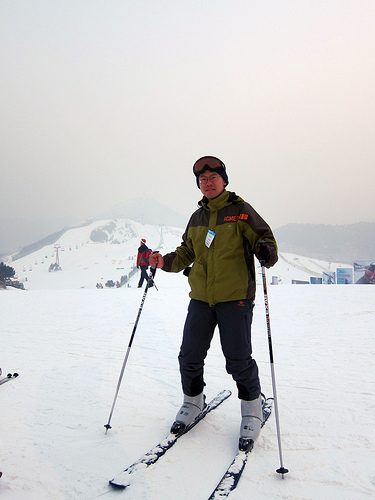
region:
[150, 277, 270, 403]
the pants are blue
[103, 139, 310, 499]
man holding two ski poles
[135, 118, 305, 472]
man on skis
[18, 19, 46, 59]
white clouds in blue sky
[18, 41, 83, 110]
white clouds in blue sky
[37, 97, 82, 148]
white clouds in blue sky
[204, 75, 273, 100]
white clouds in blue sky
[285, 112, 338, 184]
white clouds in blue sky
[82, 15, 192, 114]
white clouds in blue sky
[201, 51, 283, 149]
white clouds in blue sky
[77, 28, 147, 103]
white clouds in blue sky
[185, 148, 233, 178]
Ski goggles on his head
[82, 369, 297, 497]
The man is wearing skis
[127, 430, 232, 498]
There is snow resting on top of his skis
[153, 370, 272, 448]
The man is wearing snow boots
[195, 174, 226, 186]
The man is wearing glasses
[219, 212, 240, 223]
The man's jacket says acme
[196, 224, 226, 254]
The man is wearing a lift tag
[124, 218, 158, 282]
This person is walking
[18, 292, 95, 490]
The ground is covered in snow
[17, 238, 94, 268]
Ski lift in this distance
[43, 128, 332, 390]
this is on a mountain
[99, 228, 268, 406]
the man is a skier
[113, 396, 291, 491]
these skies are black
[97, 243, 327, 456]
these are ski poles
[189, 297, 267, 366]
the man's pants are black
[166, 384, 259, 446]
the boots are gray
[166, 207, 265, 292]
the man's jacket is green and black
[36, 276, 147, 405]
this snow is deep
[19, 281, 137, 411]
this snow is very bright white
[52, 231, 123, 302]
the mountain slope is covered in snow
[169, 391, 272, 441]
man wearing gray snow boots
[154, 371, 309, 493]
man on a ski slope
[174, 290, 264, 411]
man wearing black pants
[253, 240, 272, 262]
man with gloves on his hand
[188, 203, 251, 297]
man wearing a green jacket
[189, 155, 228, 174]
man with ski googles on his head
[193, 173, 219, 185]
man wearing wire eye glasses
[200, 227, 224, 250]
man with a tag on his jacket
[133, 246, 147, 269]
person wearing a red jacket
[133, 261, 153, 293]
person wearing black pants